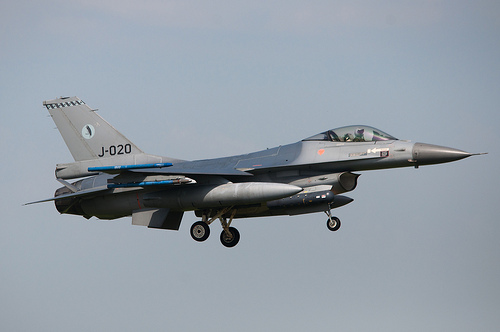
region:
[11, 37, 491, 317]
The plane is in the air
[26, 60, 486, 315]
The plane is carrying a pilot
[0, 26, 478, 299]
The plane is for the military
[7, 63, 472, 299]
The plane is a military aircraft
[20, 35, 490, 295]
The plane is for making war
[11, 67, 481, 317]
A plane is for dropping bombs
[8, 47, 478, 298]
The plane is loaded with ordinance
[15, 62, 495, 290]
The plane is a jet aircraft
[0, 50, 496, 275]
The plane is a military fighter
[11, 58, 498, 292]
The plane is looking for enemies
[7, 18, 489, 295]
The military aircraft is flying high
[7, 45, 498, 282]
The aircraft belongs to the military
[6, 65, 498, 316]
The plane is designed for warfare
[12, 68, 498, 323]
The plane is carrying weapons for war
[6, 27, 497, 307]
The plane is flying very fast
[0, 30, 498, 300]
The plane is filled with jet fuel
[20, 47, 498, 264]
The plane is going to the base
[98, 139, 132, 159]
J-020 in black lettering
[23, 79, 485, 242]
Black and grey jet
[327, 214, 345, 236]
Black and white tire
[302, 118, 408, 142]
Cockpit of the plane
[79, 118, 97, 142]
Blue and black logo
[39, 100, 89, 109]
Checkered banned on tail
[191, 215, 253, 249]
Two hind black wheels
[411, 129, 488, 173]
Black nose of plane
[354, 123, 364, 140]
Pilot of air plane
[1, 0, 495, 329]
Clear sky in the color of blue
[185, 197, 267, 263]
wheels on a jet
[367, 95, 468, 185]
the nose of a jet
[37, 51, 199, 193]
the back end of a jet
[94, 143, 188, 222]
missiles on a jet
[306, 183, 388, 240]
the front wheel on a jet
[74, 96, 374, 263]
a jet in the air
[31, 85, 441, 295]
a flying jet in the sky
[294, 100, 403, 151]
the window on a jet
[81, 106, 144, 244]
writing on a jet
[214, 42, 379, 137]
a clear blue sky